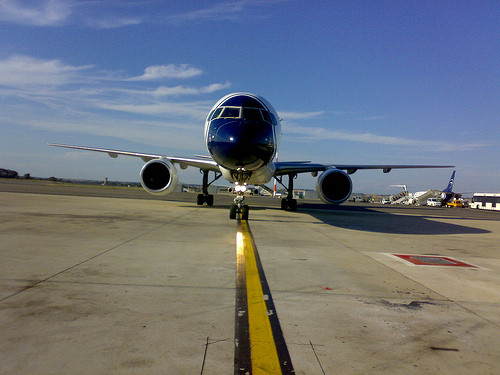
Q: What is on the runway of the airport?
A: The airplane.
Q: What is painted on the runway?
A: The yellow and black line.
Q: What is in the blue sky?
A: The white clouds.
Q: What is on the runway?
A: Yellow and black.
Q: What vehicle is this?
A: Plane.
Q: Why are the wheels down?
A: For takeoff or landing.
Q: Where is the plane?
A: On the yellow line.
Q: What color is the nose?
A: Navy blue.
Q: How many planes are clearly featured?
A: One.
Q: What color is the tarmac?
A: Grey.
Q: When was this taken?
A: During the day.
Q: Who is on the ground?
A: No one.